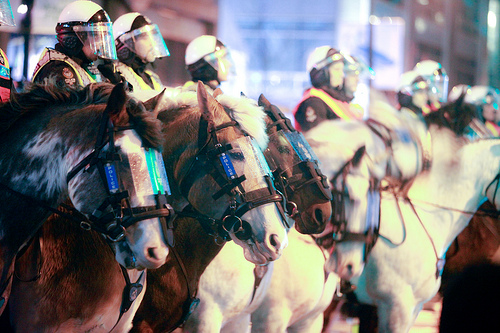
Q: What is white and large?
A: The horse.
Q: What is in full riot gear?
A: The mounted police.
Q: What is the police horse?
A: White.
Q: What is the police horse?
A: Palomino.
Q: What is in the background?
A: The city building.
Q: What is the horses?
A: The row.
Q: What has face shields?
A: Cops.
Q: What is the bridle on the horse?
A: Black.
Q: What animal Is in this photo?
A: Horses.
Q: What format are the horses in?
A: A line.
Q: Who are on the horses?
A: Cops.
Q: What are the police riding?
A: Horses.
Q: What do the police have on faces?
A: Shields.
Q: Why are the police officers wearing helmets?
A: For protection.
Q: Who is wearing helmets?
A: The police.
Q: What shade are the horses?
A: Brown and white.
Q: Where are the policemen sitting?
A: On horses.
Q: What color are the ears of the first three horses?
A: Brown.